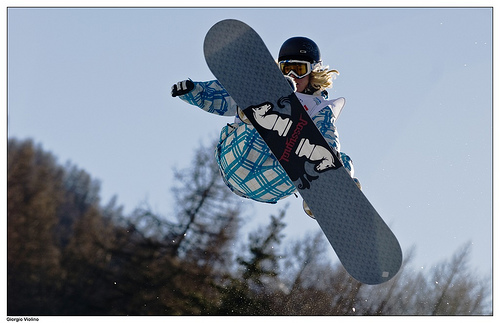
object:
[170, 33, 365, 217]
snow boarder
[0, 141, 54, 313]
evergreen tree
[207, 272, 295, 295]
snow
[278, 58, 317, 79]
goggles